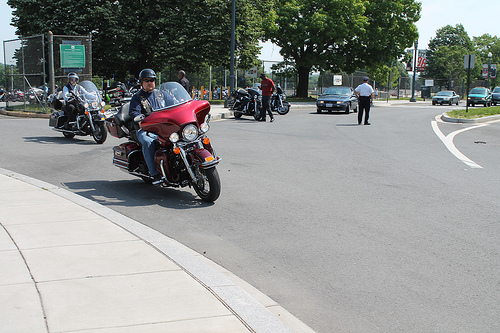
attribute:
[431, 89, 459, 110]
car — black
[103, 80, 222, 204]
motorcycle — red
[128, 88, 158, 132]
shirt — dark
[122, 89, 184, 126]
shirt — black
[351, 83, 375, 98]
shirt — blue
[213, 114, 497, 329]
street — paved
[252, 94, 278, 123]
pants. — black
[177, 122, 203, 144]
light — large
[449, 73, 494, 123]
van — black, green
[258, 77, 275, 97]
shirt — red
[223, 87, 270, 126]
motorcycle — black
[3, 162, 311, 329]
sidewalk — paved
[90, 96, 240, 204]
motorcycle — black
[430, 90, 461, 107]
car — green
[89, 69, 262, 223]
motorcycle — red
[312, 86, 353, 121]
car — black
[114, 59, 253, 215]
motorcycle — red